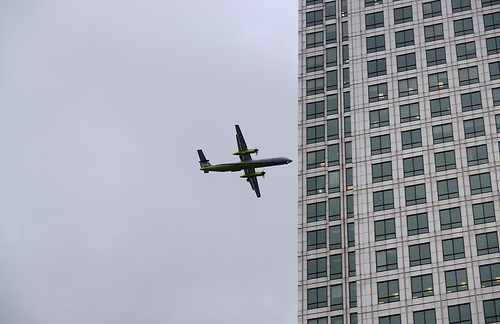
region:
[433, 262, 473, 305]
window to a building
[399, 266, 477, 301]
two windows on building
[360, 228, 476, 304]
set of windows on building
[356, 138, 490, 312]
group of windows on building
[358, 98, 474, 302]
plenty of windows on building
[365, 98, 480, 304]
several windows on building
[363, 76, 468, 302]
multiple windows on building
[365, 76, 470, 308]
many windows on building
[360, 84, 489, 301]
several windows on big building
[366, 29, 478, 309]
multiple windows on large building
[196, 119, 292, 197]
Airplane flying in the sky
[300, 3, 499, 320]
large towering building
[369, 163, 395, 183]
Window in large building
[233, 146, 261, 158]
Large airplane engine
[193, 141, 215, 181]
Large tail portraying from airplane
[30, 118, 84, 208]
Pale blue sky background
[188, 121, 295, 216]
Large airplane flying toward building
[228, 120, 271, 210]
Wings of an airplane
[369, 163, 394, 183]
Two plains of glass in window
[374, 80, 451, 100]
Interior lights of building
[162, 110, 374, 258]
a plane is flying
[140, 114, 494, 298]
a plane is flying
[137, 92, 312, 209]
a plane is flying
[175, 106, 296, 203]
airplane in the sky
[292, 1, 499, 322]
tall building with many windows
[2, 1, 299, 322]
light gray sky covered in clouds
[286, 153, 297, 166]
pointed nose of the plane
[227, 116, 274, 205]
two long plane wings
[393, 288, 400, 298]
light visible in the window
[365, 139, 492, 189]
row of four windows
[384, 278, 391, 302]
thin black window pane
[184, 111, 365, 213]
plane flying by a building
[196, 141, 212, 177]
tail of the airplane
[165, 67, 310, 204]
plane in the sky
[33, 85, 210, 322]
the sky is cloudy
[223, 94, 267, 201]
the plane is near the building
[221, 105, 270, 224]
plane has two wings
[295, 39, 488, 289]
the building is tall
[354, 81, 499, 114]
the lights are on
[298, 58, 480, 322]
the building has windows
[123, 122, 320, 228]
the plane is flying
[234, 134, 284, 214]
the plane has two propellers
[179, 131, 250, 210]
the plane has tail